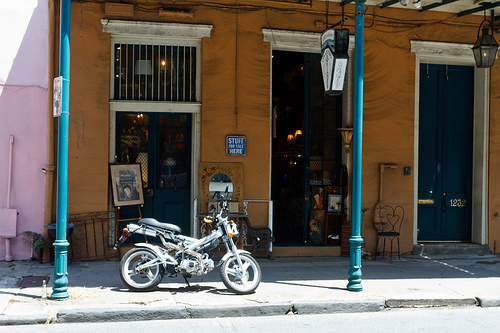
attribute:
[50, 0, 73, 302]
post — blue, for support, metal, tall, bright blue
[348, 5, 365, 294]
post — blue, for support, metal, tall, bright blue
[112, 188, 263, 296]
motorcyle — parked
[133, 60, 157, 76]
lampsade — white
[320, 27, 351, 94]
sign — suspended, for business, bright blue, wedge shaped, hanging, white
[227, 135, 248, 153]
sign — square, semi grungey, blue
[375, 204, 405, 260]
chair — black, metal, framed, vintage vanity, vanity, stablized, wobbly, child sized, wrought iron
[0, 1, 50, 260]
facade — pink, dusty rose, dusy pink, panted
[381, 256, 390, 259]
stopper — small, bright red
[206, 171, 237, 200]
mirror — round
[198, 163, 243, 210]
frame — ornate, painted, sqaure, wood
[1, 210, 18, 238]
fusebox — pink, painted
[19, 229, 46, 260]
plant — small, large leafed, growning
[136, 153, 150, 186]
lampsade — alight, yellow, orange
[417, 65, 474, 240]
door — blue, half opened, tall, closed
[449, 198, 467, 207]
number — white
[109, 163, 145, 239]
easel — displaying art, painted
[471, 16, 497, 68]
lamp — hanging, old fashioned, black iron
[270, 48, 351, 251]
doorway — open